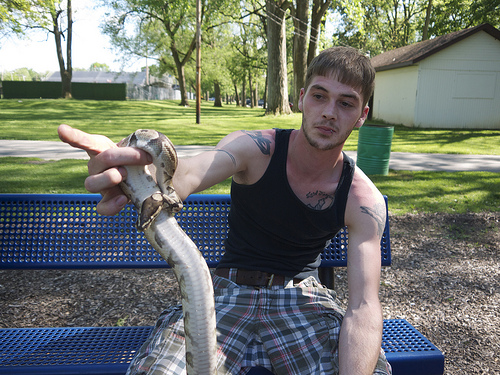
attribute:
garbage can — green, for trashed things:
[356, 121, 396, 179]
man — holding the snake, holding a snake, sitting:
[58, 47, 398, 374]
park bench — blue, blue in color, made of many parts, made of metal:
[1, 191, 446, 374]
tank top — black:
[217, 128, 354, 285]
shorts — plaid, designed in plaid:
[129, 270, 393, 374]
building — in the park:
[363, 20, 500, 132]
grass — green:
[3, 99, 500, 192]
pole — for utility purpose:
[193, 1, 205, 131]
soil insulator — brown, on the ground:
[6, 211, 493, 374]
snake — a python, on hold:
[118, 130, 220, 374]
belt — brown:
[214, 267, 320, 287]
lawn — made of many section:
[2, 95, 499, 331]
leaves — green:
[2, 0, 500, 54]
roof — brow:
[369, 22, 500, 70]